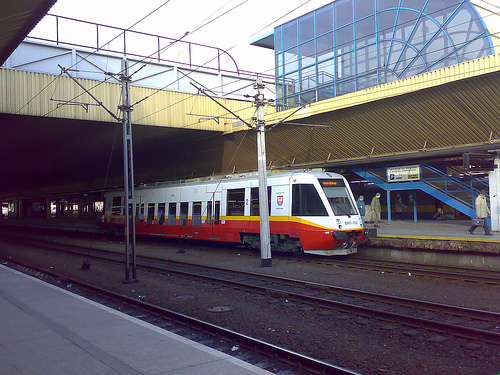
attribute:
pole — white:
[257, 134, 270, 258]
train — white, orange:
[150, 170, 353, 250]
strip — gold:
[221, 212, 261, 224]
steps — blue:
[390, 168, 474, 208]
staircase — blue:
[399, 162, 471, 215]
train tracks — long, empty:
[169, 253, 333, 318]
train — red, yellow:
[134, 178, 366, 258]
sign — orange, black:
[316, 174, 346, 188]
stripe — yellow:
[214, 211, 305, 233]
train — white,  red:
[100, 168, 360, 265]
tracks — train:
[351, 250, 484, 299]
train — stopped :
[103, 175, 354, 255]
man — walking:
[469, 190, 484, 230]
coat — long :
[476, 194, 484, 220]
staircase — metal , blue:
[363, 172, 482, 228]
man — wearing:
[472, 189, 484, 234]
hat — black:
[469, 187, 484, 198]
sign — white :
[381, 167, 424, 185]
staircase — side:
[357, 164, 478, 227]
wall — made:
[267, 19, 484, 138]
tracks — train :
[344, 255, 484, 288]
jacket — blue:
[353, 197, 369, 218]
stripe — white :
[7, 263, 232, 369]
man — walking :
[470, 193, 484, 237]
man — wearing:
[460, 183, 484, 238]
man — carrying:
[471, 187, 484, 244]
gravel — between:
[208, 294, 369, 341]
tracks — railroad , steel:
[203, 271, 462, 361]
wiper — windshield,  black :
[326, 200, 358, 216]